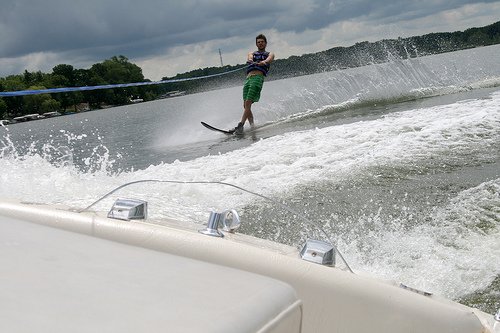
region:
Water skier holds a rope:
[221, 25, 279, 141]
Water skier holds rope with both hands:
[217, 29, 289, 146]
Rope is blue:
[0, 57, 257, 103]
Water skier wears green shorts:
[222, 25, 284, 142]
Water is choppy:
[69, 48, 499, 238]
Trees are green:
[5, 59, 155, 118]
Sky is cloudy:
[7, 5, 239, 58]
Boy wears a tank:
[218, 21, 292, 145]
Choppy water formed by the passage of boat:
[96, 111, 499, 270]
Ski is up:
[188, 110, 237, 146]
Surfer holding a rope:
[215, 27, 293, 140]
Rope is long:
[7, 51, 253, 113]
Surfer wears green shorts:
[224, 28, 279, 143]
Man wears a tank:
[222, 28, 293, 139]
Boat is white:
[5, 157, 499, 332]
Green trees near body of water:
[6, 57, 149, 121]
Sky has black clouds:
[3, 0, 487, 40]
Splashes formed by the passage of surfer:
[287, 39, 461, 114]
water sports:
[8, 14, 497, 309]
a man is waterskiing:
[19, 31, 453, 302]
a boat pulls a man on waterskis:
[27, 17, 422, 313]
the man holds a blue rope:
[16, 16, 291, 148]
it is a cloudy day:
[23, 2, 497, 56]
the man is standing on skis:
[14, 22, 311, 169]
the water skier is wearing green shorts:
[202, 30, 293, 147]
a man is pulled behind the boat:
[29, 34, 426, 319]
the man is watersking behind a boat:
[34, 19, 468, 316]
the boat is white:
[10, 184, 484, 329]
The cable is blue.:
[70, 81, 159, 104]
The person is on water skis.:
[197, 118, 237, 142]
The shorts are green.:
[227, 88, 259, 108]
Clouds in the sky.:
[317, 28, 371, 42]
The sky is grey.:
[23, 17, 84, 46]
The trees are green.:
[23, 78, 96, 104]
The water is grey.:
[115, 98, 185, 128]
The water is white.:
[175, 165, 243, 195]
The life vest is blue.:
[234, 44, 272, 69]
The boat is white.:
[91, 266, 143, 305]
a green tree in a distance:
[21, 82, 47, 113]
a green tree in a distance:
[43, 93, 63, 110]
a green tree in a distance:
[2, 77, 22, 110]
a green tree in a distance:
[109, 64, 133, 97]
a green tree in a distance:
[53, 59, 82, 96]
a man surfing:
[221, 13, 283, 137]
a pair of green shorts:
[241, 74, 267, 99]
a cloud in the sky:
[136, 48, 193, 88]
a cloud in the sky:
[312, 10, 364, 53]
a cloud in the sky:
[16, 16, 116, 56]